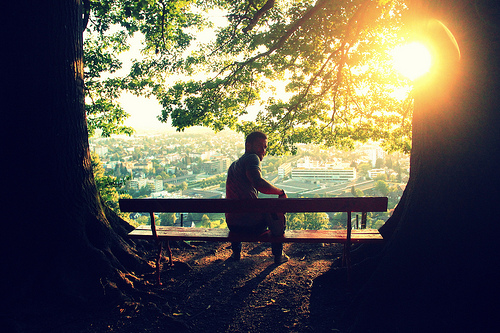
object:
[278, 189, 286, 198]
wristwatch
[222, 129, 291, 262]
person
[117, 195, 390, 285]
bench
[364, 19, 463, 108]
sun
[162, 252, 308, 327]
dirt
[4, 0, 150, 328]
tree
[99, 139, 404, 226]
city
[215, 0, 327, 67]
branch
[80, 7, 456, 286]
scene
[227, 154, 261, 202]
tshirt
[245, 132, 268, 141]
hair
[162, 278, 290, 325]
ground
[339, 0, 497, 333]
trees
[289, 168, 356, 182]
building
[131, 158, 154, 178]
house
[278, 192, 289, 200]
hand